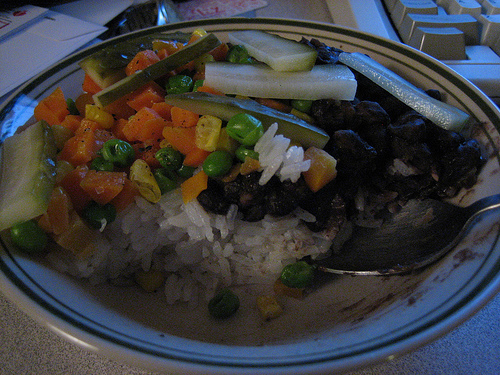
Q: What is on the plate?
A: Food.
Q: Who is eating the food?
A: No one.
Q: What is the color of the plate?
A: White.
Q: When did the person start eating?
A: Earlier.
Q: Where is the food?
A: On the table.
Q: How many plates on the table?
A: One.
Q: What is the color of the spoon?
A: Silver.